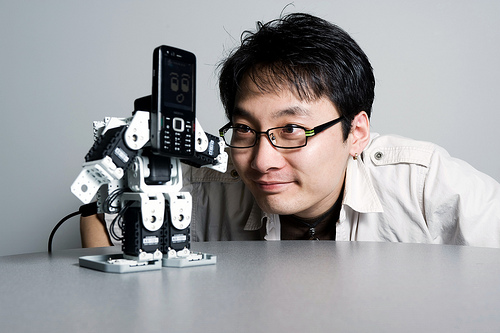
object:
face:
[222, 81, 347, 213]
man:
[74, 14, 499, 248]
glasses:
[215, 124, 324, 151]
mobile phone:
[152, 42, 195, 162]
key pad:
[164, 144, 175, 149]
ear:
[351, 112, 371, 157]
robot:
[75, 46, 231, 272]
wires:
[48, 214, 67, 244]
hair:
[221, 15, 377, 129]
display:
[162, 60, 197, 107]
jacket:
[98, 138, 498, 239]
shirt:
[275, 217, 337, 247]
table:
[5, 239, 499, 327]